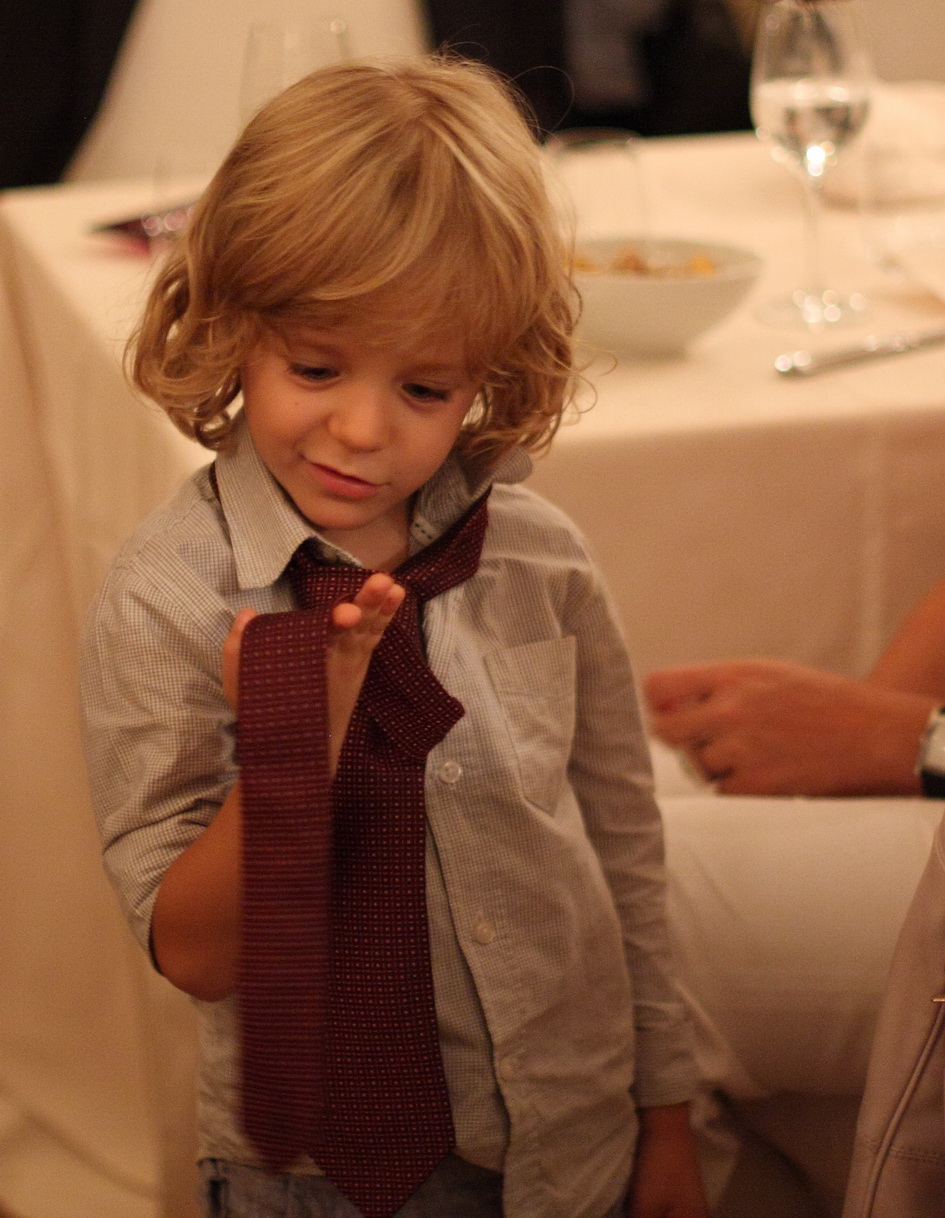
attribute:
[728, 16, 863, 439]
glass — wine glass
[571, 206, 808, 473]
bowl — white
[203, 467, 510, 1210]
tie — red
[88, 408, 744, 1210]
shirt — collared, grey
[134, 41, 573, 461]
hair — curly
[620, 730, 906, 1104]
pants — white